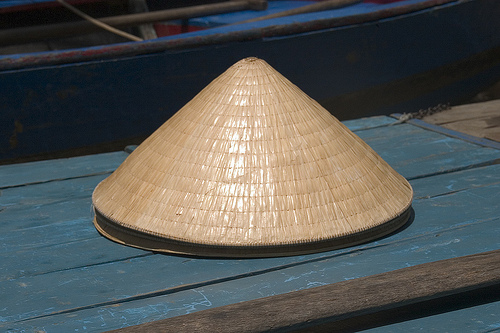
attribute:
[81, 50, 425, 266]
hats — brown, conical, bamboo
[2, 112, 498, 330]
wooden table — blue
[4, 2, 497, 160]
boat — blue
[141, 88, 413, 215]
hat — straw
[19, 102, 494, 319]
table — brown, wooden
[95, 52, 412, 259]
pointed hat — tan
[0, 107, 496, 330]
table — blue, outdoor table, wooden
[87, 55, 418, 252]
hat — asian, straw, bamboo, conical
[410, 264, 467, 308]
oars — brown, wooden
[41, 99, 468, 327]
slab — wooden, turquoise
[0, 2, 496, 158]
row boat — blue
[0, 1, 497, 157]
paint — red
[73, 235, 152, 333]
table — painted